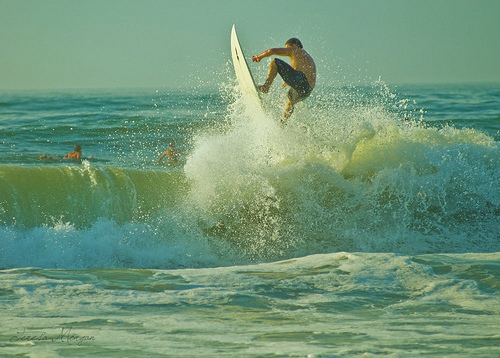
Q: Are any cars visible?
A: No, there are no cars.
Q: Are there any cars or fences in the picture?
A: No, there are no cars or fences.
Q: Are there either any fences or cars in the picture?
A: No, there are no cars or fences.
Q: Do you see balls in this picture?
A: No, there are no balls.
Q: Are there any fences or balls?
A: No, there are no balls or fences.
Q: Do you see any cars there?
A: No, there are no cars.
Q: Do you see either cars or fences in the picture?
A: No, there are no cars or fences.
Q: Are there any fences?
A: No, there are no fences.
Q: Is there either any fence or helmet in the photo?
A: No, there are no fences or helmets.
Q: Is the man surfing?
A: Yes, the man is surfing.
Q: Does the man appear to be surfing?
A: Yes, the man is surfing.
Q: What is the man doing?
A: The man is surfing.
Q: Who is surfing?
A: The man is surfing.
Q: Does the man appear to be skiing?
A: No, the man is surfing.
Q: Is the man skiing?
A: No, the man is surfing.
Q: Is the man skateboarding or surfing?
A: The man is surfing.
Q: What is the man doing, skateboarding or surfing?
A: The man is surfing.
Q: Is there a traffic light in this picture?
A: No, there are no traffic lights.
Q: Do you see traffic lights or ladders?
A: No, there are no traffic lights or ladders.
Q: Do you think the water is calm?
A: Yes, the water is calm.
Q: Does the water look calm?
A: Yes, the water is calm.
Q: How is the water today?
A: The water is calm.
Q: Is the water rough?
A: No, the water is calm.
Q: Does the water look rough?
A: No, the water is calm.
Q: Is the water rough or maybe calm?
A: The water is calm.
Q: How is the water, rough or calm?
A: The water is calm.